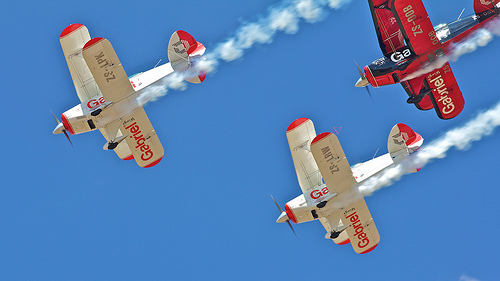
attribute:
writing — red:
[122, 120, 154, 164]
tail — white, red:
[152, 31, 224, 95]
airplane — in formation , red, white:
[41, 20, 215, 172]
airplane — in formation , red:
[268, 113, 425, 255]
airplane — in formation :
[346, 0, 498, 123]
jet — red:
[48, 21, 210, 168]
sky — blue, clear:
[0, 0, 499, 280]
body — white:
[55, 54, 194, 132]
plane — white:
[47, 20, 214, 171]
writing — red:
[118, 119, 164, 179]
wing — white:
[83, 120, 174, 163]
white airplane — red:
[39, 20, 215, 166]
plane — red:
[358, 1, 498, 123]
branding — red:
[120, 106, 170, 176]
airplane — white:
[240, 97, 440, 279]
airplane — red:
[26, 16, 246, 183]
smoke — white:
[231, 18, 287, 46]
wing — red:
[421, 79, 469, 149]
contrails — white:
[21, 19, 220, 189]